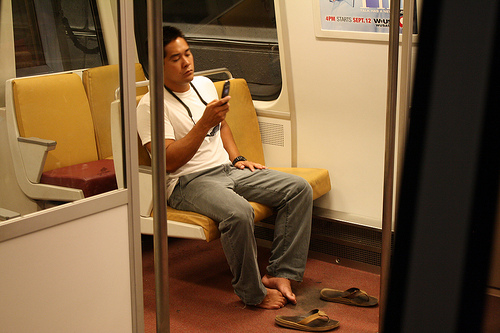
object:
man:
[135, 25, 314, 310]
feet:
[249, 286, 284, 310]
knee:
[278, 174, 314, 209]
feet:
[259, 271, 301, 308]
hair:
[135, 25, 188, 82]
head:
[136, 25, 194, 86]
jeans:
[165, 161, 314, 306]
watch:
[232, 154, 246, 167]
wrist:
[228, 154, 248, 164]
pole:
[143, 0, 171, 332]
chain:
[163, 88, 198, 124]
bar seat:
[113, 67, 226, 91]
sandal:
[272, 307, 341, 332]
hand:
[199, 95, 232, 130]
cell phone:
[220, 80, 232, 99]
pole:
[374, 0, 399, 332]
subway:
[0, 0, 498, 332]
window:
[158, 0, 280, 47]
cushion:
[36, 157, 119, 199]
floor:
[135, 232, 380, 332]